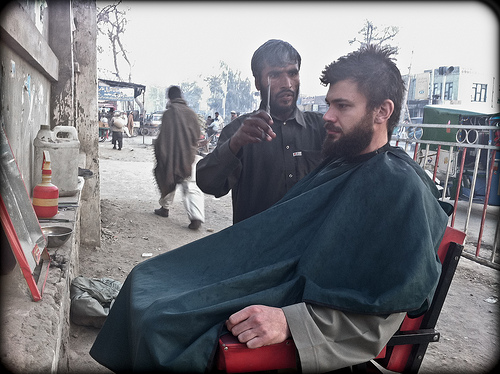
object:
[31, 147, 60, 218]
can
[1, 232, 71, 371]
ledge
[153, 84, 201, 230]
man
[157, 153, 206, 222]
pants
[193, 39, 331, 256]
man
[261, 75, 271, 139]
scissors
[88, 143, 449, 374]
cape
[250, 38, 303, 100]
hair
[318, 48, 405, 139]
hair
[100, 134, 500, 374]
ground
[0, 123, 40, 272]
mirror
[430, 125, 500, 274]
rails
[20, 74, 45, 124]
woman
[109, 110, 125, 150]
person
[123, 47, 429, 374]
man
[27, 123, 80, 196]
can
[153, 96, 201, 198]
blanket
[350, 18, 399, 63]
tree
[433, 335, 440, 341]
bolt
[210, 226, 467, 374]
chair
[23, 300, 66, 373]
wall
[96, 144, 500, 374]
street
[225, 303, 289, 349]
hand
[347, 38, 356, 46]
leaf